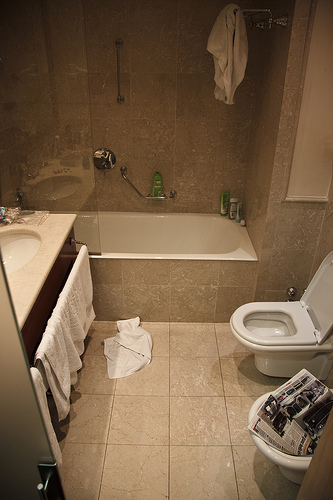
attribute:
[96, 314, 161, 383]
towel — white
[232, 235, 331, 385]
toilet — white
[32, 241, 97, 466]
towel — white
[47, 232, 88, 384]
bar — towel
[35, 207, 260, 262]
bathtub — white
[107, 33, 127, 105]
bar — chrome, safety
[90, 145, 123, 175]
knob — chrome, control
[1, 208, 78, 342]
counter — beige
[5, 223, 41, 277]
sink — white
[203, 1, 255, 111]
towel — hanging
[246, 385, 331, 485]
basket — white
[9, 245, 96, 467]
towels — white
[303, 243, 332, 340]
lid — toilet, up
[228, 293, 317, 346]
toilet seat — down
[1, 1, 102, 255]
glass door — sliding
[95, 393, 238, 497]
tiles — cream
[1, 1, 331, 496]
bathroom — beige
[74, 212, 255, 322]
bathtub — white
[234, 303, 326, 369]
toilet bowl — white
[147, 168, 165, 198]
green bottle — shampoo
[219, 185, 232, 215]
green bottle — conditioner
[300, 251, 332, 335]
lid — up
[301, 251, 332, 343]
toilet lid — up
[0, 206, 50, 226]
bag — plastic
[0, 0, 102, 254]
shower door — glass